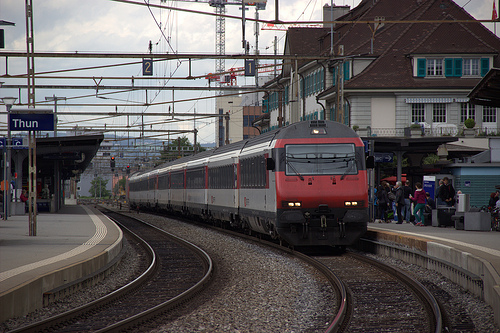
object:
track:
[0, 198, 216, 333]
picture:
[0, 0, 500, 332]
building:
[262, 0, 500, 205]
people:
[376, 179, 391, 224]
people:
[391, 179, 403, 226]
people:
[484, 191, 500, 232]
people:
[19, 187, 28, 206]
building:
[243, 105, 268, 140]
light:
[284, 201, 295, 207]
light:
[343, 198, 351, 206]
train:
[123, 119, 373, 253]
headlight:
[293, 201, 305, 210]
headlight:
[350, 199, 359, 207]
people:
[409, 182, 427, 227]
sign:
[142, 58, 154, 78]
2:
[144, 61, 151, 72]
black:
[354, 229, 366, 240]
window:
[412, 103, 425, 122]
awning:
[403, 95, 473, 104]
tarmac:
[368, 221, 500, 285]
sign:
[7, 110, 59, 130]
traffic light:
[109, 153, 117, 173]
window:
[424, 55, 434, 74]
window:
[471, 57, 481, 77]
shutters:
[416, 56, 429, 77]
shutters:
[442, 56, 454, 75]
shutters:
[479, 57, 491, 75]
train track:
[11, 198, 444, 332]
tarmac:
[0, 199, 125, 297]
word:
[12, 117, 43, 129]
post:
[93, 153, 151, 159]